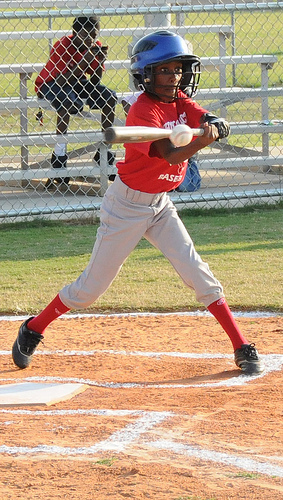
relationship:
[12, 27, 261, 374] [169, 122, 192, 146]
he hit ball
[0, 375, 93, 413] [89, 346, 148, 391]
home plate on dirt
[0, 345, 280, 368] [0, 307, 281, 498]
stripe in dirt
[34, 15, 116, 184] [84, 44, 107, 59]
spectator holding phone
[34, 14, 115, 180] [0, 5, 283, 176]
boy sitting on bleachers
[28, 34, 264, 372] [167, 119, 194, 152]
boy hitting baseball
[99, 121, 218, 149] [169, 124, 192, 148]
baseball bat striking ball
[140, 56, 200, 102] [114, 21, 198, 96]
face guard on helmet